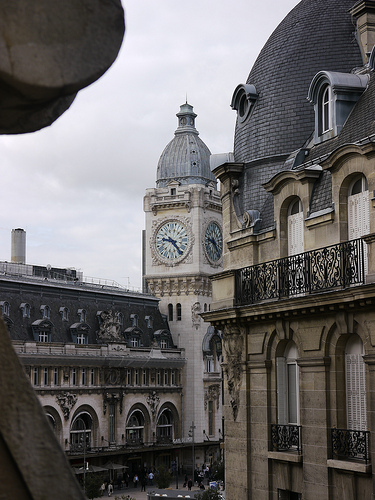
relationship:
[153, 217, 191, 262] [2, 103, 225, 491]
clock on building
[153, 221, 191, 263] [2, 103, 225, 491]
clock on building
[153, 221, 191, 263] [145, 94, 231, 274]
clock on tower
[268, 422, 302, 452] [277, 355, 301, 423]
metal railing outside window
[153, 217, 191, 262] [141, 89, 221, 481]
clock on a building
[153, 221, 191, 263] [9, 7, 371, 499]
clock on a building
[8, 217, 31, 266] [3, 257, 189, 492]
smoke stack behind building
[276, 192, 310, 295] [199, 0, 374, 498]
arched window in top of building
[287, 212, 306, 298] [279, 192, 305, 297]
shutters on arched window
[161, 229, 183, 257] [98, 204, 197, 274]
hands on clock